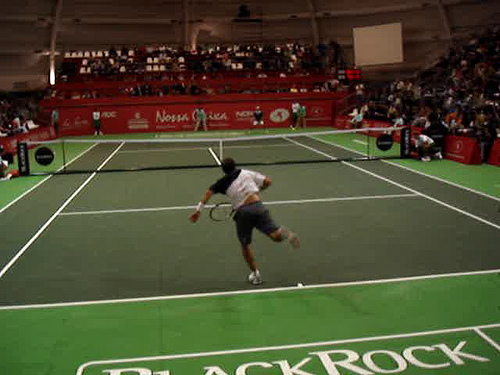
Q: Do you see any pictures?
A: No, there are no pictures.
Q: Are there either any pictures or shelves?
A: No, there are no pictures or shelves.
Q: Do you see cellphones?
A: No, there are no cellphones.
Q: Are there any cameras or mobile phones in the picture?
A: No, there are no mobile phones or cameras.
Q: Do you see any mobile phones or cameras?
A: No, there are no mobile phones or cameras.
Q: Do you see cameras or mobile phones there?
A: No, there are no mobile phones or cameras.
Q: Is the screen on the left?
A: No, the screen is on the right of the image.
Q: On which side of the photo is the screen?
A: The screen is on the right of the image.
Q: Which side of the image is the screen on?
A: The screen is on the right of the image.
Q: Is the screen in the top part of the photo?
A: Yes, the screen is in the top of the image.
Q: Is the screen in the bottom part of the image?
A: No, the screen is in the top of the image.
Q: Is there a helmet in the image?
A: No, there are no helmets.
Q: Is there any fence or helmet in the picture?
A: No, there are no helmets or fences.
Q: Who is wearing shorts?
A: The player is wearing shorts.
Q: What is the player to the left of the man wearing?
A: The player is wearing shorts.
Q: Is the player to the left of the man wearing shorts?
A: Yes, the player is wearing shorts.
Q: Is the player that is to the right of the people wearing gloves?
A: No, the player is wearing shorts.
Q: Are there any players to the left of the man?
A: Yes, there is a player to the left of the man.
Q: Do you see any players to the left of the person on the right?
A: Yes, there is a player to the left of the man.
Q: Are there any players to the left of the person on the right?
A: Yes, there is a player to the left of the man.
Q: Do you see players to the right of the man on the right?
A: No, the player is to the left of the man.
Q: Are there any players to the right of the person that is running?
A: No, the player is to the left of the man.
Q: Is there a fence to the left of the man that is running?
A: No, there is a player to the left of the man.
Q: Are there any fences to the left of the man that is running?
A: No, there is a player to the left of the man.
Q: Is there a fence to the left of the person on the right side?
A: No, there is a player to the left of the man.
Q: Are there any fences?
A: No, there are no fences.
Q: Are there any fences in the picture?
A: No, there are no fences.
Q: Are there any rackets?
A: Yes, there is a racket.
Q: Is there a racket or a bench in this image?
A: Yes, there is a racket.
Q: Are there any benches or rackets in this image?
A: Yes, there is a racket.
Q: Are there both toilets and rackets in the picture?
A: No, there is a racket but no toilets.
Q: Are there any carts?
A: No, there are no carts.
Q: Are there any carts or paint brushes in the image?
A: No, there are no carts or paint brushes.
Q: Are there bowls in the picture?
A: No, there are no bowls.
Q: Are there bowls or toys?
A: No, there are no bowls or toys.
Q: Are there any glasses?
A: No, there are no glasses.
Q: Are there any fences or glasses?
A: No, there are no glasses or fences.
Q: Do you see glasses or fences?
A: No, there are no glasses or fences.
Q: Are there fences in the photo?
A: No, there are no fences.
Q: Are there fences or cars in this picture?
A: No, there are no fences or cars.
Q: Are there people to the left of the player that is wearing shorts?
A: Yes, there are people to the left of the player.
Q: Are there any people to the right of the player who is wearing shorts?
A: No, the people are to the left of the player.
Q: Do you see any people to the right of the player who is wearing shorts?
A: No, the people are to the left of the player.